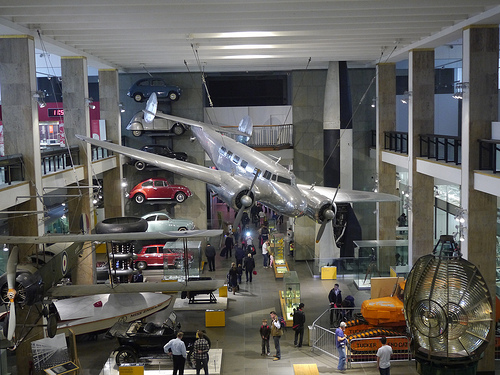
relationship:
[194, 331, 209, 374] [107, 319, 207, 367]
man looking at an car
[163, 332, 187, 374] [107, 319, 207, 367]
man looking at an car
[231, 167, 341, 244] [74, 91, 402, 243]
propellers of airplane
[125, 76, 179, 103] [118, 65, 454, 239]
vw bug on a wall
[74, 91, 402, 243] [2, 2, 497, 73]
airplane hanging from ceiling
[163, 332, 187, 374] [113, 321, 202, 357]
man standing by car